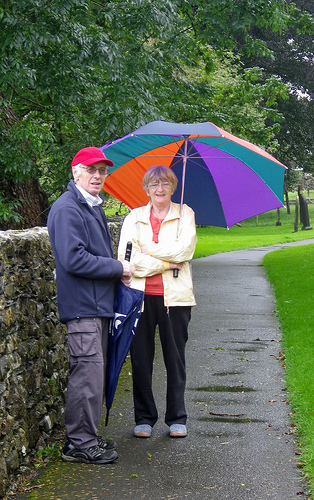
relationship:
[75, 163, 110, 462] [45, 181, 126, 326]
man wearing jacket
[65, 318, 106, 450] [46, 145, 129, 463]
pants on man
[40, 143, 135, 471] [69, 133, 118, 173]
man wearing hat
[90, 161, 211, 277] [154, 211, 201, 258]
woman wearing yellow top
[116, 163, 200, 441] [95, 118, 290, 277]
woman holding umbrella